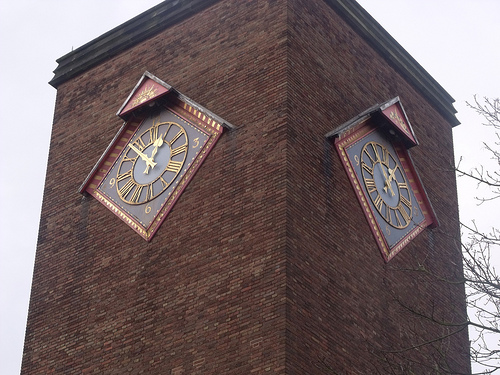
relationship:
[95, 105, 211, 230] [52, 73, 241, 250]
clock face of clock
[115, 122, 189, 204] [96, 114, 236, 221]
roman numerals on clock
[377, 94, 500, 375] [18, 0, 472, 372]
bare tree next to brick tower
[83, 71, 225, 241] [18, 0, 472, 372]
clock on left side of brick tower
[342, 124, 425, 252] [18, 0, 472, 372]
clock on right side of brick tower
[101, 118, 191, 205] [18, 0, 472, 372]
clock face on brick tower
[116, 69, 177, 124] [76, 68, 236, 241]
ornament above clock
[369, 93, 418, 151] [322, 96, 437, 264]
ornament above clock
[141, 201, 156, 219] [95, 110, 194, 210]
number on clock face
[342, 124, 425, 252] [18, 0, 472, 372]
clock on brick tower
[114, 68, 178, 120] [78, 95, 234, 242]
triangle on top of clock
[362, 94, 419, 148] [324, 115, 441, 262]
triangle on top of clock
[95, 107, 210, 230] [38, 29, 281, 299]
clock on wall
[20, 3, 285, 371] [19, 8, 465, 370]
brown wall indicating structure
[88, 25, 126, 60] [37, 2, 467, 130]
border indicating roof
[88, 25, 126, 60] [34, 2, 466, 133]
border indicating railing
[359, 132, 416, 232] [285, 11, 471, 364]
clock on side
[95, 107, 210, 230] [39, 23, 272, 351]
clock on side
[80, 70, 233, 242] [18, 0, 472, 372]
ornate design on brick tower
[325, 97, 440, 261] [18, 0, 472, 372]
ornate design on brick tower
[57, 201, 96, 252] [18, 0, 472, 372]
brick on brick tower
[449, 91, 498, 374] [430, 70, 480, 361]
branches of tree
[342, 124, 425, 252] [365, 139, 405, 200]
clock reads 12:49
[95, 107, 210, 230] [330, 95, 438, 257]
clock indicates time